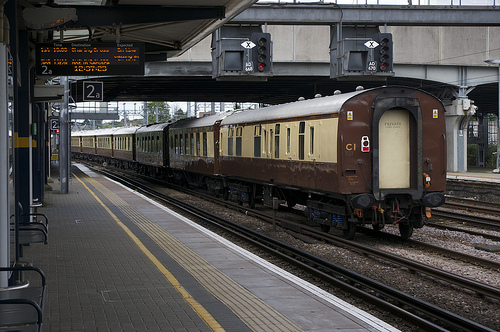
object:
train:
[71, 84, 448, 238]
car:
[218, 86, 449, 240]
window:
[298, 121, 305, 160]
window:
[275, 123, 281, 158]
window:
[235, 127, 242, 157]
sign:
[36, 40, 145, 78]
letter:
[95, 92, 100, 98]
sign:
[82, 80, 103, 101]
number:
[86, 85, 94, 98]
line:
[71, 172, 224, 331]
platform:
[1, 155, 382, 332]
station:
[1, 2, 496, 330]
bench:
[0, 267, 48, 330]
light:
[258, 63, 266, 71]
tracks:
[81, 160, 500, 295]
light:
[377, 33, 394, 74]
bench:
[14, 200, 50, 258]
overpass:
[1, 0, 500, 96]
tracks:
[16, 153, 405, 332]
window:
[253, 125, 262, 157]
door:
[380, 109, 412, 189]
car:
[169, 110, 235, 197]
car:
[133, 120, 176, 177]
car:
[113, 124, 146, 170]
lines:
[80, 170, 303, 332]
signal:
[252, 31, 272, 72]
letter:
[345, 143, 353, 151]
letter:
[353, 144, 356, 151]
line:
[99, 173, 402, 332]